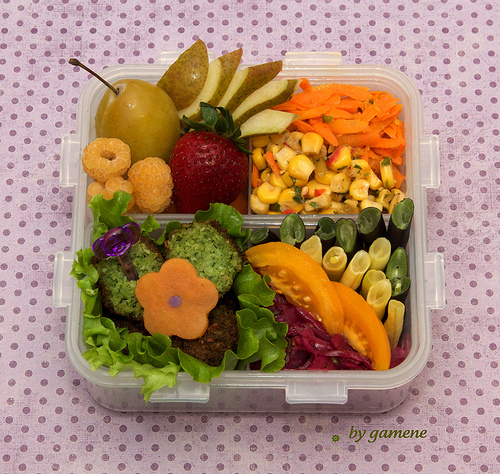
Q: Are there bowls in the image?
A: No, there are no bowls.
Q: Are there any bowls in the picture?
A: No, there are no bowls.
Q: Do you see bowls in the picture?
A: No, there are no bowls.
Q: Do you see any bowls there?
A: No, there are no bowls.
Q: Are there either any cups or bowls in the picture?
A: No, there are no bowls or cups.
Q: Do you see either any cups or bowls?
A: No, there are no bowls or cups.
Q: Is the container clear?
A: Yes, the container is clear.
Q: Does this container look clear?
A: Yes, the container is clear.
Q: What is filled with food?
A: The container is filled with food.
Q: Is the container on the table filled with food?
A: Yes, the container is filled with food.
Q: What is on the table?
A: The container is on the table.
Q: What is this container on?
A: The container is on the table.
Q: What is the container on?
A: The container is on the table.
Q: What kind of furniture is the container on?
A: The container is on the table.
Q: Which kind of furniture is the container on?
A: The container is on the table.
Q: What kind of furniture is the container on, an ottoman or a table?
A: The container is on a table.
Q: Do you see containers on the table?
A: Yes, there is a container on the table.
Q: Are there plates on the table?
A: No, there is a container on the table.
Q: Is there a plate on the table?
A: No, there is a container on the table.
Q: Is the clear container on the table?
A: Yes, the container is on the table.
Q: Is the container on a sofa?
A: No, the container is on the table.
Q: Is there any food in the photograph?
A: Yes, there is food.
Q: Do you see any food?
A: Yes, there is food.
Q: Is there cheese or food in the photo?
A: Yes, there is food.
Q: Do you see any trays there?
A: No, there are no trays.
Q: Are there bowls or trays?
A: No, there are no trays or bowls.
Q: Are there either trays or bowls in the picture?
A: No, there are no trays or bowls.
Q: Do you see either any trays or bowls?
A: No, there are no trays or bowls.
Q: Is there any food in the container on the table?
A: Yes, there is food in the container.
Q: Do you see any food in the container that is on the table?
A: Yes, there is food in the container.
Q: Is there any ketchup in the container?
A: No, there is food in the container.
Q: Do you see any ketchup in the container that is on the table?
A: No, there is food in the container.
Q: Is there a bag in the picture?
A: No, there are no bags.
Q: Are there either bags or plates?
A: No, there are no bags or plates.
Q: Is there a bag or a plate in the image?
A: No, there are no bags or plates.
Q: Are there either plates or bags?
A: No, there are no bags or plates.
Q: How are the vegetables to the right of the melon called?
A: The vegetables are beets.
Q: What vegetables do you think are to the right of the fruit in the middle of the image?
A: The vegetables are beets.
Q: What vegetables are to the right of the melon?
A: The vegetables are beets.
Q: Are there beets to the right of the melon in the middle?
A: Yes, there are beets to the right of the melon.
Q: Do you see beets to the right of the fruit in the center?
A: Yes, there are beets to the right of the melon.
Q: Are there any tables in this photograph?
A: Yes, there is a table.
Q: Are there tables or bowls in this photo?
A: Yes, there is a table.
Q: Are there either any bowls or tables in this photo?
A: Yes, there is a table.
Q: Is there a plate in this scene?
A: No, there are no plates.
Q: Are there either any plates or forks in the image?
A: No, there are no plates or forks.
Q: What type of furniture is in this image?
A: The furniture is a table.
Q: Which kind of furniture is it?
A: The piece of furniture is a table.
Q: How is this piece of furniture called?
A: This is a table.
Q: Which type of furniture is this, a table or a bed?
A: This is a table.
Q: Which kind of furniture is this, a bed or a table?
A: This is a table.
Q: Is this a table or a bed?
A: This is a table.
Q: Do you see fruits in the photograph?
A: Yes, there is a fruit.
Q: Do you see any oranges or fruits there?
A: Yes, there is a fruit.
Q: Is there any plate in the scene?
A: No, there are no plates.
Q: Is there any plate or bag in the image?
A: No, there are no plates or bags.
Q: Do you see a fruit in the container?
A: Yes, there is a fruit in the container.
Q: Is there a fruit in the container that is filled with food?
A: Yes, there is a fruit in the container.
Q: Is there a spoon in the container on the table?
A: No, there is a fruit in the container.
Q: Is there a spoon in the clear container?
A: No, there is a fruit in the container.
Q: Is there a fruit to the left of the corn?
A: Yes, there is a fruit to the left of the corn.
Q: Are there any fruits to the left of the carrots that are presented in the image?
A: Yes, there is a fruit to the left of the carrots.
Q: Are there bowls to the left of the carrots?
A: No, there is a fruit to the left of the carrots.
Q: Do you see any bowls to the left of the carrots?
A: No, there is a fruit to the left of the carrots.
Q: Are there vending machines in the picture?
A: No, there are no vending machines.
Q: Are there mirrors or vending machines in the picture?
A: No, there are no vending machines or mirrors.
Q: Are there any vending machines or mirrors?
A: No, there are no vending machines or mirrors.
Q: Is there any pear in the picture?
A: Yes, there is a pear.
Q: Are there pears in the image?
A: Yes, there is a pear.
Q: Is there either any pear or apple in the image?
A: Yes, there is a pear.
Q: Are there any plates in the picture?
A: No, there are no plates.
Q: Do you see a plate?
A: No, there are no plates.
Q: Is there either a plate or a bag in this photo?
A: No, there are no plates or bags.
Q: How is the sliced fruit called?
A: The fruit is a pear.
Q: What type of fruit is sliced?
A: The fruit is a pear.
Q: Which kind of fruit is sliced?
A: The fruit is a pear.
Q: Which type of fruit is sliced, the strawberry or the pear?
A: The pear is sliced.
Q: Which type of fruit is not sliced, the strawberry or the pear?
A: The strawberry is not sliced.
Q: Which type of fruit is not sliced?
A: The fruit is a strawberry.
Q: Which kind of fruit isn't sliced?
A: The fruit is a strawberry.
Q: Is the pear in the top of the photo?
A: Yes, the pear is in the top of the image.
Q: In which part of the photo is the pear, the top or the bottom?
A: The pear is in the top of the image.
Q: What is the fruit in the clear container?
A: The fruit is a pear.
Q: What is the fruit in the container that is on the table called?
A: The fruit is a pear.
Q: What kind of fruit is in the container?
A: The fruit is a pear.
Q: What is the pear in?
A: The pear is in the container.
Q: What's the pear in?
A: The pear is in the container.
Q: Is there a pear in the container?
A: Yes, there is a pear in the container.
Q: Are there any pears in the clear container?
A: Yes, there is a pear in the container.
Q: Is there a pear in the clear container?
A: Yes, there is a pear in the container.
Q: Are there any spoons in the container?
A: No, there is a pear in the container.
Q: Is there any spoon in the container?
A: No, there is a pear in the container.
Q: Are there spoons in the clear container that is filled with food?
A: No, there is a pear in the container.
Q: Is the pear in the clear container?
A: Yes, the pear is in the container.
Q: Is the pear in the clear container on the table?
A: Yes, the pear is in the container.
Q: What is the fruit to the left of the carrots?
A: The fruit is a pear.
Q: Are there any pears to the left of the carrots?
A: Yes, there is a pear to the left of the carrots.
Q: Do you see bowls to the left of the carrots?
A: No, there is a pear to the left of the carrots.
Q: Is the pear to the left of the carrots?
A: Yes, the pear is to the left of the carrots.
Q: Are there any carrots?
A: Yes, there are carrots.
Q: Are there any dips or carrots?
A: Yes, there are carrots.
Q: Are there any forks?
A: No, there are no forks.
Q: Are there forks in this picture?
A: No, there are no forks.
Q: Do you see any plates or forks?
A: No, there are no forks or plates.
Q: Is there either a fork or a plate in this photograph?
A: No, there are no forks or plates.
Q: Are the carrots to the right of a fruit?
A: Yes, the carrots are to the right of a fruit.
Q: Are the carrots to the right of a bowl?
A: No, the carrots are to the right of a fruit.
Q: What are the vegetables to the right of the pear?
A: The vegetables are carrots.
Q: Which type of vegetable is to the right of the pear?
A: The vegetables are carrots.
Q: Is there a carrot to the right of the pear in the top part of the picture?
A: Yes, there are carrots to the right of the pear.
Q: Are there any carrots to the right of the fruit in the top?
A: Yes, there are carrots to the right of the pear.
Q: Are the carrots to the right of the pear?
A: Yes, the carrots are to the right of the pear.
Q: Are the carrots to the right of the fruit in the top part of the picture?
A: Yes, the carrots are to the right of the pear.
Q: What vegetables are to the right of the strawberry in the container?
A: The vegetables are carrots.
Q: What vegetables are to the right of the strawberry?
A: The vegetables are carrots.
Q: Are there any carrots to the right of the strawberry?
A: Yes, there are carrots to the right of the strawberry.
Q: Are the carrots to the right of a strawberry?
A: Yes, the carrots are to the right of a strawberry.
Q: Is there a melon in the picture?
A: Yes, there is a melon.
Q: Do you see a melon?
A: Yes, there is a melon.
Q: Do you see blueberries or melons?
A: Yes, there is a melon.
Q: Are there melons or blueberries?
A: Yes, there is a melon.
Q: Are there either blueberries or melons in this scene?
A: Yes, there is a melon.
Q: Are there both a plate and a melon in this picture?
A: No, there is a melon but no plates.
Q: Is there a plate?
A: No, there are no plates.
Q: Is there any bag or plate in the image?
A: No, there are no plates or bags.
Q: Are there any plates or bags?
A: No, there are no plates or bags.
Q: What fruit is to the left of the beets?
A: The fruit is a melon.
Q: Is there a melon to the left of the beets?
A: Yes, there is a melon to the left of the beets.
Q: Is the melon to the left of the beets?
A: Yes, the melon is to the left of the beets.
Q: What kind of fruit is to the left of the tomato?
A: The fruit is a melon.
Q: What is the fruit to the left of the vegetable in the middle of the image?
A: The fruit is a melon.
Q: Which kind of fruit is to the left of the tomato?
A: The fruit is a melon.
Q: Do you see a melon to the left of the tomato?
A: Yes, there is a melon to the left of the tomato.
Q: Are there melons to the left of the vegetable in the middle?
A: Yes, there is a melon to the left of the tomato.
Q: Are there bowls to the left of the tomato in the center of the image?
A: No, there is a melon to the left of the tomato.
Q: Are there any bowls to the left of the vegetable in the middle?
A: No, there is a melon to the left of the tomato.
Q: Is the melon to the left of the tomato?
A: Yes, the melon is to the left of the tomato.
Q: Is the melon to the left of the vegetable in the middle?
A: Yes, the melon is to the left of the tomato.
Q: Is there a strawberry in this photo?
A: Yes, there is a strawberry.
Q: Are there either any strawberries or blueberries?
A: Yes, there is a strawberry.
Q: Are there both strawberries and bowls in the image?
A: No, there is a strawberry but no bowls.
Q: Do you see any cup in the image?
A: No, there are no cups.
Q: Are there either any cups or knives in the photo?
A: No, there are no cups or knives.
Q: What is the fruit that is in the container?
A: The fruit is a strawberry.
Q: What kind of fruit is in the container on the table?
A: The fruit is a strawberry.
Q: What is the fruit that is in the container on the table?
A: The fruit is a strawberry.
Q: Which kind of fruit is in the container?
A: The fruit is a strawberry.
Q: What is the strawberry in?
A: The strawberry is in the container.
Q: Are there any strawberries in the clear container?
A: Yes, there is a strawberry in the container.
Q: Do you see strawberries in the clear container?
A: Yes, there is a strawberry in the container.